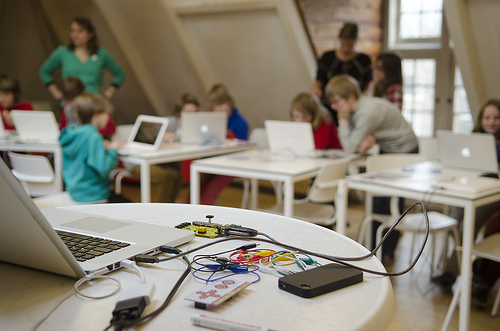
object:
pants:
[130, 166, 183, 203]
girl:
[37, 16, 126, 110]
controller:
[184, 279, 250, 307]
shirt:
[36, 44, 125, 108]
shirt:
[58, 123, 118, 203]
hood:
[57, 124, 95, 160]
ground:
[416, 107, 468, 134]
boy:
[57, 93, 135, 204]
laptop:
[179, 110, 227, 145]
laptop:
[263, 119, 324, 158]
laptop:
[436, 130, 498, 174]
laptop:
[9, 110, 63, 145]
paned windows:
[400, 0, 440, 39]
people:
[470, 98, 500, 170]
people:
[313, 21, 374, 127]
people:
[363, 51, 404, 119]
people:
[201, 83, 248, 141]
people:
[162, 93, 200, 143]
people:
[0, 75, 35, 130]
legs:
[189, 166, 201, 204]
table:
[190, 148, 367, 219]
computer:
[116, 114, 170, 156]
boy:
[324, 74, 421, 155]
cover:
[0, 156, 85, 279]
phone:
[278, 263, 363, 299]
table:
[0, 201, 396, 331]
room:
[0, 0, 498, 331]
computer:
[0, 156, 195, 281]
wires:
[143, 253, 192, 324]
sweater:
[335, 95, 417, 154]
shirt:
[378, 85, 402, 115]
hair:
[373, 51, 402, 97]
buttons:
[115, 242, 130, 247]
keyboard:
[50, 229, 130, 263]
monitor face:
[133, 121, 162, 145]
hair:
[65, 18, 99, 56]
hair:
[338, 22, 358, 41]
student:
[366, 51, 404, 114]